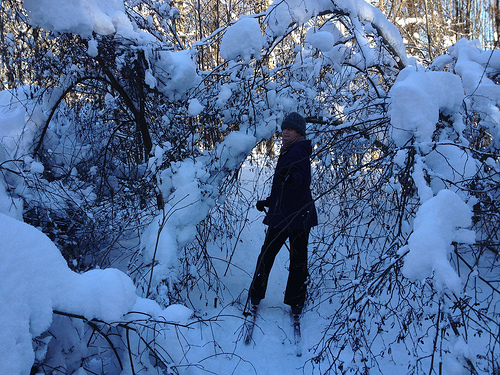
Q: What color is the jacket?
A: Black.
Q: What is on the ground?
A: Snow.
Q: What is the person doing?
A: Looking at camera.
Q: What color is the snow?
A: White.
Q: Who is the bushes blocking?
A: Skier.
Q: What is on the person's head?
A: Cap.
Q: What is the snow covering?
A: Branches.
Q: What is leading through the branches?
A: Path.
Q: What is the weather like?
A: Cold.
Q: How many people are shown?
A: One.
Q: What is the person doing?
A: Skiing.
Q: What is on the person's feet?
A: Skis.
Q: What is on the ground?
A: Snow.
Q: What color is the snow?
A: White.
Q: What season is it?
A: Winter.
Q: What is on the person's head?
A: A hat.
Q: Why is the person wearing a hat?
A: To keep their head warm.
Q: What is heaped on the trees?
A: Snow.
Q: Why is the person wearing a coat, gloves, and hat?
A: It's cold.